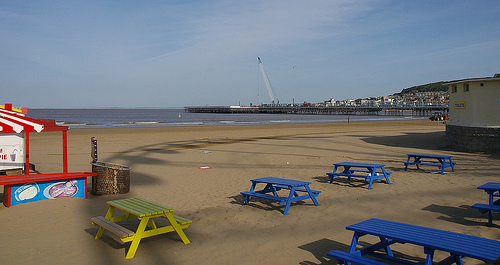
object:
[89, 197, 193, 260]
bench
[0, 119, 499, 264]
beach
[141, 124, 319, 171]
sand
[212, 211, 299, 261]
sand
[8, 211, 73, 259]
sand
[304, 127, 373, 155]
sand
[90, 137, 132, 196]
trash bin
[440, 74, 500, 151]
building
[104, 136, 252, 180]
shadow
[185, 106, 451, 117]
pier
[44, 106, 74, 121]
water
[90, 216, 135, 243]
benches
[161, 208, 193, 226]
benches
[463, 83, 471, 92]
windows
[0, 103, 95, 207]
food stand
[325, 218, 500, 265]
benches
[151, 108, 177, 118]
water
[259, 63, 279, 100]
white smoke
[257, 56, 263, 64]
jet